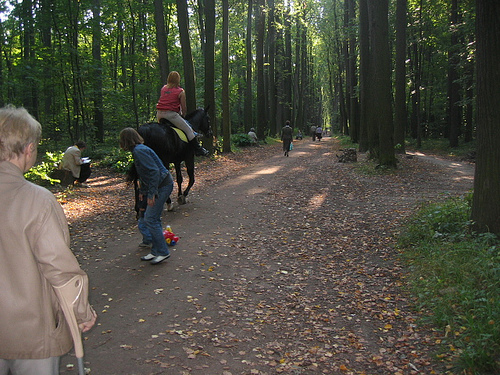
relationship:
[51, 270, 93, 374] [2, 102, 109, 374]
crutch on woman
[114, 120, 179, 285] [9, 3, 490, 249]
people in woods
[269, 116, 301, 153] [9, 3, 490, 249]
people in woods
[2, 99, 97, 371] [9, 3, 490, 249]
people in woods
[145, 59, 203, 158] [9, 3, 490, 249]
people in woods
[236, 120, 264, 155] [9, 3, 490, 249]
people in woods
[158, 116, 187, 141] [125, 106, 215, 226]
saddle on horse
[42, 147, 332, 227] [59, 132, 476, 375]
sunlight on path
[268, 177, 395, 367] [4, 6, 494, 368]
dry leaves in photo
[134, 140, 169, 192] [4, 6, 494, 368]
jacket in photo